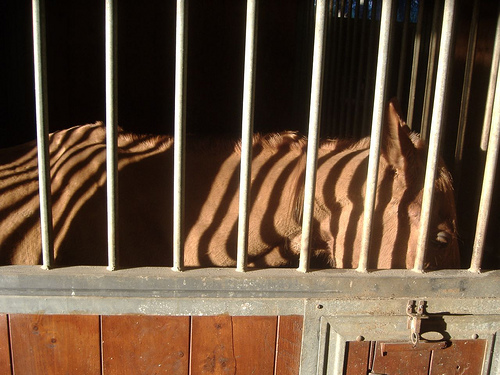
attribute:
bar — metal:
[228, 0, 268, 268]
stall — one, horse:
[0, 0, 497, 375]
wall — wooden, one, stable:
[1, 310, 305, 372]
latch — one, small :
[381, 303, 451, 343]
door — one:
[242, 87, 477, 347]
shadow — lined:
[208, 146, 425, 256]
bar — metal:
[409, 0, 455, 272]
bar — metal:
[413, 10, 449, 280]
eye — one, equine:
[433, 226, 458, 248]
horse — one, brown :
[6, 95, 473, 270]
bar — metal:
[134, 19, 207, 286]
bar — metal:
[274, 5, 355, 307]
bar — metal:
[29, 2, 55, 267]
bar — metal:
[102, 2, 118, 271]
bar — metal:
[169, 2, 185, 270]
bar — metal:
[235, 0, 255, 272]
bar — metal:
[295, 1, 326, 271]